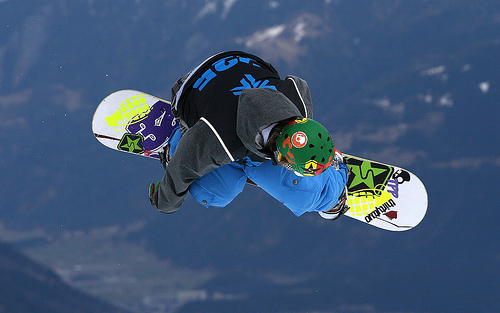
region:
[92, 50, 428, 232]
A man on a snow board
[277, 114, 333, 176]
green helmet with stickers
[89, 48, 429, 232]
young man doing a stunt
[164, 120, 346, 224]
bright blue snow pants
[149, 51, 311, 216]
hoodie with blue logo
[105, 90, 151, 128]
yellow grenade decoration on a snowboard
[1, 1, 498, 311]
slightly blury mountain scenery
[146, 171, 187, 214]
warm green glove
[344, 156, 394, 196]
green star decoration on a snowboard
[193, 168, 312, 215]
small metal snaps on snowpants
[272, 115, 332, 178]
The helmet is green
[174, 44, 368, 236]
the man is wearing pants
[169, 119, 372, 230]
the pants are blue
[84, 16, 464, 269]
the man is riding a snow board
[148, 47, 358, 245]
the man is wearing a jacket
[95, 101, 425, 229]
the snow board is colorful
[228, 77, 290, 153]
the hood is gray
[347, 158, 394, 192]
the star is green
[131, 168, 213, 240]
the man is wearing gloves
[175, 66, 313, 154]
the vest is black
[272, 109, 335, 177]
Green helmet on person snow boarding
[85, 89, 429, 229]
Long white snow board with decorations on it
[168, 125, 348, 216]
Baby blue snow pants on a person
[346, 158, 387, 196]
Green star on a snow board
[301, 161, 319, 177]
Black star with an S in it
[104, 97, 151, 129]
Yellow stencil of a grenade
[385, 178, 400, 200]
Purple letters that say TPP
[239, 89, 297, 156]
Dark gray hood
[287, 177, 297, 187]
Silver button on blue snow pants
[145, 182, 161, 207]
Part of a green glove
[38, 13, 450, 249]
Snowboarder in blue pants.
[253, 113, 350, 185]
Green helmet on snowboarder's head.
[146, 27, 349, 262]
Snowboarder in the air doing a trick.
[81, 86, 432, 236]
White snowboard with stickers.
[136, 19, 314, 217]
Grey hoodies with a black vest over it.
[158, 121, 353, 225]
Blue snowpants on the snowboarder.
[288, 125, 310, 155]
Red sticker on the green helmet.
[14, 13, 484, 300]
Mountains in the background.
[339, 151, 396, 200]
Black sticker with a green star.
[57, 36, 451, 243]
Snowboarder flying in the air.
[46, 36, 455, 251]
person in the air doing snowboarding trick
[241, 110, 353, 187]
green helmet on snowboarder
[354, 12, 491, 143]
mountain tops covered with snow behind snowboarder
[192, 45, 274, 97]
blue lettering on snowboarders jacket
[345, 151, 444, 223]
white snowboard with brightly color designs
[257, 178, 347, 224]
light blue ski pants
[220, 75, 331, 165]
grey hood on jacket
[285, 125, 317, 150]
round red sticker on green helmet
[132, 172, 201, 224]
gloves covering hands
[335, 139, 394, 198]
green star on snowboard